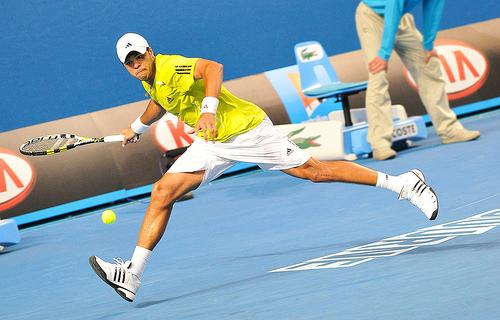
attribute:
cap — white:
[115, 32, 150, 63]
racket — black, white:
[15, 128, 138, 160]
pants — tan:
[352, 12, 466, 143]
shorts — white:
[166, 111, 307, 188]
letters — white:
[262, 207, 497, 277]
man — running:
[74, 30, 366, 285]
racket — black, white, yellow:
[21, 131, 153, 159]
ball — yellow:
[99, 203, 136, 228]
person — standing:
[348, 0, 485, 156]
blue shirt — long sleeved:
[360, 0, 457, 64]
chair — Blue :
[298, 42, 360, 108]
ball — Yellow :
[97, 203, 115, 225]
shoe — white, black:
[82, 248, 150, 300]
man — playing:
[87, 30, 438, 302]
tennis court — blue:
[0, 74, 499, 318]